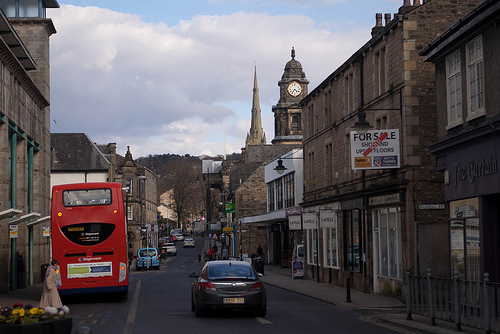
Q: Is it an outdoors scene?
A: Yes, it is outdoors.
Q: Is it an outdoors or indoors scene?
A: It is outdoors.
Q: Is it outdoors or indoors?
A: It is outdoors.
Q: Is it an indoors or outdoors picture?
A: It is outdoors.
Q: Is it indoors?
A: No, it is outdoors.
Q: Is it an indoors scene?
A: No, it is outdoors.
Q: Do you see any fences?
A: Yes, there is a fence.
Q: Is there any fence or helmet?
A: Yes, there is a fence.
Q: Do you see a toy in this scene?
A: No, there are no toys.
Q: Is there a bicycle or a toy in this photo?
A: No, there are no toys or bicycles.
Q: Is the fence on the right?
A: Yes, the fence is on the right of the image.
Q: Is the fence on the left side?
A: No, the fence is on the right of the image.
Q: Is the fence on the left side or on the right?
A: The fence is on the right of the image.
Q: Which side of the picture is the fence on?
A: The fence is on the right of the image.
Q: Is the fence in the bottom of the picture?
A: Yes, the fence is in the bottom of the image.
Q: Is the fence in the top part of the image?
A: No, the fence is in the bottom of the image.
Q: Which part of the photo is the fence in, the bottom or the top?
A: The fence is in the bottom of the image.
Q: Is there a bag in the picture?
A: No, there are no bags.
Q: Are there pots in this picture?
A: Yes, there is a pot.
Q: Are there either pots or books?
A: Yes, there is a pot.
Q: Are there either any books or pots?
A: Yes, there is a pot.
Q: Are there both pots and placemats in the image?
A: No, there is a pot but no placemats.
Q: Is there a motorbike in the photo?
A: No, there are no motorcycles.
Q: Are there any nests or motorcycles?
A: No, there are no motorcycles or nests.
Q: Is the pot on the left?
A: Yes, the pot is on the left of the image.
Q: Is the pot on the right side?
A: No, the pot is on the left of the image.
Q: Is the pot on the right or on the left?
A: The pot is on the left of the image.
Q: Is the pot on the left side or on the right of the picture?
A: The pot is on the left of the image.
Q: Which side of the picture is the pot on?
A: The pot is on the left of the image.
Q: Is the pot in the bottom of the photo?
A: Yes, the pot is in the bottom of the image.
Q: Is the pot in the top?
A: No, the pot is in the bottom of the image.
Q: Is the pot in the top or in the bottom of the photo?
A: The pot is in the bottom of the image.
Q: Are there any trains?
A: No, there are no trains.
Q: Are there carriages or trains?
A: No, there are no trains or carriages.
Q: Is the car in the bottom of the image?
A: Yes, the car is in the bottom of the image.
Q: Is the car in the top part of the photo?
A: No, the car is in the bottom of the image.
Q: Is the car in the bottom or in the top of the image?
A: The car is in the bottom of the image.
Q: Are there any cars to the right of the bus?
A: Yes, there is a car to the right of the bus.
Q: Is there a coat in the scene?
A: Yes, there is a coat.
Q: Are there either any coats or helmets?
A: Yes, there is a coat.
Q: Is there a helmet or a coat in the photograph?
A: Yes, there is a coat.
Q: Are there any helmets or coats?
A: Yes, there is a coat.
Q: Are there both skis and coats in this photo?
A: No, there is a coat but no skis.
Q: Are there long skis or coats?
A: Yes, there is a long coat.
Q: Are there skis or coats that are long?
A: Yes, the coat is long.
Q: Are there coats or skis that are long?
A: Yes, the coat is long.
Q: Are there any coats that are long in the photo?
A: Yes, there is a long coat.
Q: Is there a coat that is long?
A: Yes, there is a coat that is long.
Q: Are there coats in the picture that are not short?
A: Yes, there is a long coat.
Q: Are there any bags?
A: No, there are no bags.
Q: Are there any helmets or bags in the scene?
A: No, there are no bags or helmets.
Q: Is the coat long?
A: Yes, the coat is long.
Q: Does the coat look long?
A: Yes, the coat is long.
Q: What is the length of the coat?
A: The coat is long.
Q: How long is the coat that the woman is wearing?
A: The coat is long.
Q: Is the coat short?
A: No, the coat is long.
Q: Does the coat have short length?
A: No, the coat is long.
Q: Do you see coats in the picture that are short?
A: No, there is a coat but it is long.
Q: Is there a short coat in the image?
A: No, there is a coat but it is long.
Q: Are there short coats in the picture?
A: No, there is a coat but it is long.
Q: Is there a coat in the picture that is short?
A: No, there is a coat but it is long.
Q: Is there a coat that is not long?
A: No, there is a coat but it is long.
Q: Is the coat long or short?
A: The coat is long.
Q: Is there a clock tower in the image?
A: Yes, there is a clock tower.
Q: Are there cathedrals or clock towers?
A: Yes, there is a clock tower.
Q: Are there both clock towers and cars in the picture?
A: Yes, there are both a clock tower and a car.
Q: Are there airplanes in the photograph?
A: No, there are no airplanes.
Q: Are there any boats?
A: No, there are no boats.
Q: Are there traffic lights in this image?
A: No, there are no traffic lights.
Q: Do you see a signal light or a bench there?
A: No, there are no traffic lights or benches.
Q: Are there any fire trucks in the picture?
A: No, there are no fire trucks.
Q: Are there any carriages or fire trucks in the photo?
A: No, there are no fire trucks or carriages.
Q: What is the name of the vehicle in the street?
A: The vehicle is a car.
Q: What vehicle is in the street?
A: The vehicle is a car.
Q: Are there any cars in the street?
A: Yes, there is a car in the street.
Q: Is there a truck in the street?
A: No, there is a car in the street.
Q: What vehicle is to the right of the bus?
A: The vehicle is a car.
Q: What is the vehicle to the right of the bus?
A: The vehicle is a car.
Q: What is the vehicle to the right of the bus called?
A: The vehicle is a car.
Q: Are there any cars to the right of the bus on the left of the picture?
A: Yes, there is a car to the right of the bus.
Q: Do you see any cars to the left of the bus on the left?
A: No, the car is to the right of the bus.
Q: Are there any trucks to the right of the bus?
A: No, there is a car to the right of the bus.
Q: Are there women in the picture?
A: Yes, there is a woman.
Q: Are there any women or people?
A: Yes, there is a woman.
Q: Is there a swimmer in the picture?
A: No, there are no swimmers.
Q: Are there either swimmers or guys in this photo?
A: No, there are no swimmers or guys.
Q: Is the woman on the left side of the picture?
A: Yes, the woman is on the left of the image.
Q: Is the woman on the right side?
A: No, the woman is on the left of the image.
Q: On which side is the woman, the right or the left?
A: The woman is on the left of the image.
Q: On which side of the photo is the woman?
A: The woman is on the left of the image.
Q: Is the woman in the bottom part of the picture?
A: Yes, the woman is in the bottom of the image.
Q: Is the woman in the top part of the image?
A: No, the woman is in the bottom of the image.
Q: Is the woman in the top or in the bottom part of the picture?
A: The woman is in the bottom of the image.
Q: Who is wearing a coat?
A: The woman is wearing a coat.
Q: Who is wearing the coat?
A: The woman is wearing a coat.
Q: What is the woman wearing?
A: The woman is wearing a coat.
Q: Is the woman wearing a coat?
A: Yes, the woman is wearing a coat.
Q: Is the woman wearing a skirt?
A: No, the woman is wearing a coat.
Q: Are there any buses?
A: Yes, there is a bus.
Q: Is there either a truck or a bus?
A: Yes, there is a bus.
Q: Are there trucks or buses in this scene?
A: Yes, there is a bus.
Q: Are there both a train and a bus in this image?
A: No, there is a bus but no trains.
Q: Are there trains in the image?
A: No, there are no trains.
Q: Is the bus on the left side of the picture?
A: Yes, the bus is on the left of the image.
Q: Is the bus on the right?
A: No, the bus is on the left of the image.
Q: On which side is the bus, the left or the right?
A: The bus is on the left of the image.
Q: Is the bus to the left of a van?
A: No, the bus is to the left of a car.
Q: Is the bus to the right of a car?
A: No, the bus is to the left of a car.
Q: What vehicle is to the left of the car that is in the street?
A: The vehicle is a bus.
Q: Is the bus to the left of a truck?
A: No, the bus is to the left of a car.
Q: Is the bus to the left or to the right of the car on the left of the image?
A: The bus is to the left of the car.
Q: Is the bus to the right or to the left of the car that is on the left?
A: The bus is to the left of the car.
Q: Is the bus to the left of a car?
A: Yes, the bus is to the left of a car.